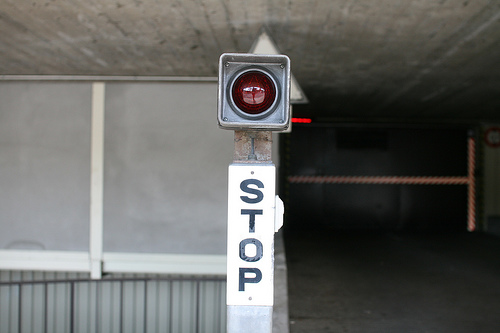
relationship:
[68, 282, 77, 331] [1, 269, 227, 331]
fence post supporting railing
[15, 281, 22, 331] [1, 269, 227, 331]
fence post supporting railing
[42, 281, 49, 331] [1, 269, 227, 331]
fence post supporting railing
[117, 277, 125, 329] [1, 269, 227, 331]
fence post supporting railing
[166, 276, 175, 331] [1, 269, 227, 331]
fence post supporting railing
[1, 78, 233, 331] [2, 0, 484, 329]
wall supporting building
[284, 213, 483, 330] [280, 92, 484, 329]
flooring laid down in area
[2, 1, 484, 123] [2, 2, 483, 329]
ceiling covering area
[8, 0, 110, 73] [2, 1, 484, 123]
groove appearing in ceiling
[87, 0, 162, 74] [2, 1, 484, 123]
groove appearing in ceiling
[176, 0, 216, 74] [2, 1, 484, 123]
groove appearing in ceiling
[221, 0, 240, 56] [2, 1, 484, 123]
groove appearing in ceiling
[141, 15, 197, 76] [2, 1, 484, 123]
groove appearing in ceiling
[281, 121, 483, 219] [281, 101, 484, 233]
wall standing in background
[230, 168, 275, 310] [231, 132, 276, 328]
sign on post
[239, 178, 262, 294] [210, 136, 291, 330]
letter on post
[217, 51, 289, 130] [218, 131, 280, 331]
light on post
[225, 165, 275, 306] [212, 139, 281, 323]
sign on post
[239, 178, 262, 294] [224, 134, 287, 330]
letter on post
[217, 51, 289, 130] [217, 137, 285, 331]
light on post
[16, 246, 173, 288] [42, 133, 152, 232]
frame on building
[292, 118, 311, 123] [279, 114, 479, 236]
illumination against a wall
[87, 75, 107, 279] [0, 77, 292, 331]
line on wall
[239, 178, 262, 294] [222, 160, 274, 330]
letter on post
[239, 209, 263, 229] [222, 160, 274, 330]
letter on post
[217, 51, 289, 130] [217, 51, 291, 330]
light on post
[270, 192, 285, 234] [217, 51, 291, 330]
paint peeling off a post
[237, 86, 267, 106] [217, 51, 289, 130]
reflection in light